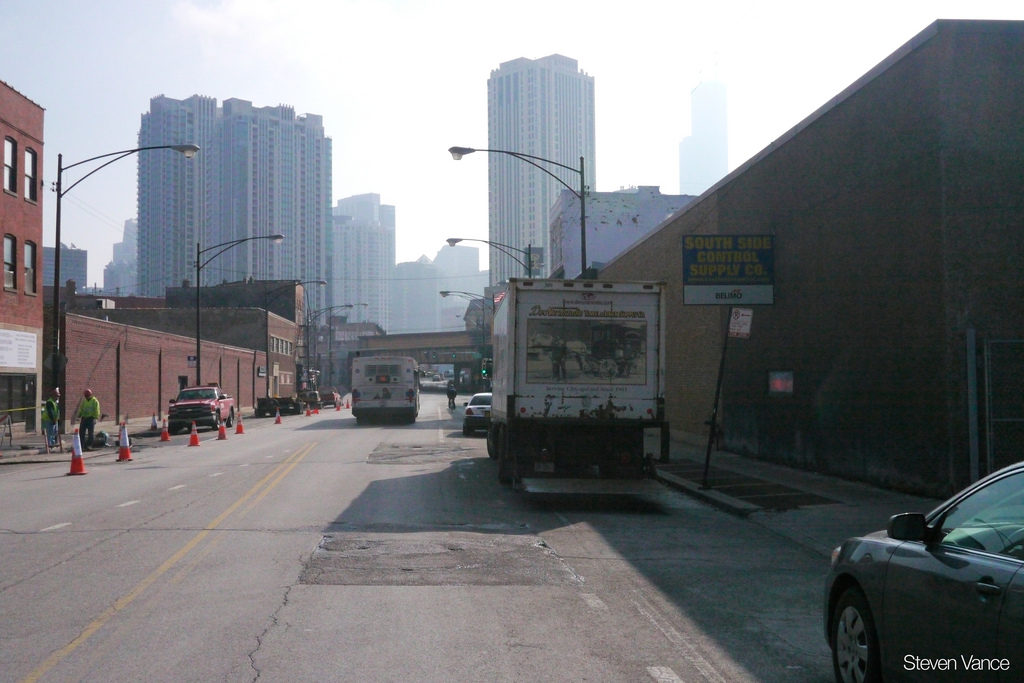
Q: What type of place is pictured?
A: It is a street.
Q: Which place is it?
A: It is a street.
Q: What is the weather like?
A: It is sunny.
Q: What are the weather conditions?
A: It is sunny.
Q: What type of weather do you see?
A: It is sunny.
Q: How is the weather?
A: It is sunny.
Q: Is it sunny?
A: Yes, it is sunny.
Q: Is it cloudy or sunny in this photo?
A: It is sunny.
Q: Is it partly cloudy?
A: No, it is sunny.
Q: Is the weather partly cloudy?
A: No, it is sunny.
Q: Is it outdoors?
A: Yes, it is outdoors.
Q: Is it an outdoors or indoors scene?
A: It is outdoors.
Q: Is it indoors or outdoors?
A: It is outdoors.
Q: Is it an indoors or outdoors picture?
A: It is outdoors.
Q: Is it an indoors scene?
A: No, it is outdoors.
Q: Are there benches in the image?
A: No, there are no benches.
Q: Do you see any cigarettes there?
A: No, there are no cigarettes.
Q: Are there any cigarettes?
A: No, there are no cigarettes.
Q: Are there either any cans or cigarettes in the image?
A: No, there are no cigarettes or cans.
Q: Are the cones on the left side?
A: Yes, the cones are on the left of the image.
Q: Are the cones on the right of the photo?
A: No, the cones are on the left of the image.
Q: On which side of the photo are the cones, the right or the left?
A: The cones are on the left of the image.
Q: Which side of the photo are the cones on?
A: The cones are on the left of the image.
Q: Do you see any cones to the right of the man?
A: Yes, there are cones to the right of the man.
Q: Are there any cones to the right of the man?
A: Yes, there are cones to the right of the man.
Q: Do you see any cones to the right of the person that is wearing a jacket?
A: Yes, there are cones to the right of the man.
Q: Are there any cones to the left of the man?
A: No, the cones are to the right of the man.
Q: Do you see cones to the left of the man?
A: No, the cones are to the right of the man.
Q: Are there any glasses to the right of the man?
A: No, there are cones to the right of the man.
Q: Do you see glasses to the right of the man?
A: No, there are cones to the right of the man.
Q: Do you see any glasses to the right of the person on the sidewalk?
A: No, there are cones to the right of the man.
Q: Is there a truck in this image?
A: Yes, there is a truck.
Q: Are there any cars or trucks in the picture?
A: Yes, there is a truck.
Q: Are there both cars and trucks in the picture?
A: Yes, there are both a truck and cars.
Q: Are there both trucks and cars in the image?
A: Yes, there are both a truck and cars.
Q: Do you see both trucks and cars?
A: Yes, there are both a truck and cars.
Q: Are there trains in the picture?
A: No, there are no trains.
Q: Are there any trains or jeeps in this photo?
A: No, there are no trains or jeeps.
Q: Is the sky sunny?
A: Yes, the sky is sunny.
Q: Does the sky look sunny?
A: Yes, the sky is sunny.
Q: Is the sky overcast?
A: No, the sky is sunny.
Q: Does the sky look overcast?
A: No, the sky is sunny.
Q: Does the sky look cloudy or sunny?
A: The sky is sunny.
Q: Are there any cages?
A: No, there are no cages.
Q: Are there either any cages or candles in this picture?
A: No, there are no cages or candles.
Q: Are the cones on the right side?
A: No, the cones are on the left of the image.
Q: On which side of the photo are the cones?
A: The cones are on the left of the image.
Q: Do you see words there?
A: Yes, there are words.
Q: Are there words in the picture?
A: Yes, there are words.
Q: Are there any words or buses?
A: Yes, there are words.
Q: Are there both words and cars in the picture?
A: Yes, there are both words and a car.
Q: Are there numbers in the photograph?
A: No, there are no numbers.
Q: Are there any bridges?
A: Yes, there is a bridge.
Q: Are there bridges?
A: Yes, there is a bridge.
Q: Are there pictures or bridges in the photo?
A: Yes, there is a bridge.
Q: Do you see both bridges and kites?
A: No, there is a bridge but no kites.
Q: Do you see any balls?
A: No, there are no balls.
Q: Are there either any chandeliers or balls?
A: No, there are no balls or chandeliers.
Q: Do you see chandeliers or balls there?
A: No, there are no balls or chandeliers.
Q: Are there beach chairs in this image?
A: No, there are no beach chairs.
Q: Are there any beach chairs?
A: No, there are no beach chairs.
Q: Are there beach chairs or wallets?
A: No, there are no beach chairs or wallets.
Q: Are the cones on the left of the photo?
A: Yes, the cones are on the left of the image.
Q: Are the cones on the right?
A: No, the cones are on the left of the image.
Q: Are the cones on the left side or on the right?
A: The cones are on the left of the image.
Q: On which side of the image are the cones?
A: The cones are on the left of the image.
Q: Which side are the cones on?
A: The cones are on the left of the image.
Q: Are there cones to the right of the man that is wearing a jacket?
A: Yes, there are cones to the right of the man.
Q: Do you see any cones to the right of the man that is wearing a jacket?
A: Yes, there are cones to the right of the man.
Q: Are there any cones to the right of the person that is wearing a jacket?
A: Yes, there are cones to the right of the man.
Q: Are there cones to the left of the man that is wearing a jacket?
A: No, the cones are to the right of the man.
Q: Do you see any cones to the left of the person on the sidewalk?
A: No, the cones are to the right of the man.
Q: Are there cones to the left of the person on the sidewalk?
A: No, the cones are to the right of the man.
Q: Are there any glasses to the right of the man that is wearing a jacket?
A: No, there are cones to the right of the man.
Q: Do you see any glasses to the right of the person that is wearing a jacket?
A: No, there are cones to the right of the man.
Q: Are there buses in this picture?
A: Yes, there is a bus.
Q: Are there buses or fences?
A: Yes, there is a bus.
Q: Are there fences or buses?
A: Yes, there is a bus.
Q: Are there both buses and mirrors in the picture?
A: Yes, there are both a bus and a mirror.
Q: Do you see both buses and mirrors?
A: Yes, there are both a bus and a mirror.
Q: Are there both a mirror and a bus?
A: Yes, there are both a bus and a mirror.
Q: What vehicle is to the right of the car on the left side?
A: The vehicle is a bus.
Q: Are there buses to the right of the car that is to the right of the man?
A: Yes, there is a bus to the right of the car.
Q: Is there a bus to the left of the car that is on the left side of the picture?
A: No, the bus is to the right of the car.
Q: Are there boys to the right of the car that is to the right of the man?
A: No, there is a bus to the right of the car.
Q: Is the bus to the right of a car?
A: Yes, the bus is to the right of a car.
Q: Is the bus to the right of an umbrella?
A: No, the bus is to the right of a car.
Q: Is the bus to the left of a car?
A: No, the bus is to the right of a car.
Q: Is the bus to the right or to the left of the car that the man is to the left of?
A: The bus is to the right of the car.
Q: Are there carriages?
A: No, there are no carriages.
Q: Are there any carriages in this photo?
A: No, there are no carriages.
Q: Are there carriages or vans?
A: No, there are no carriages or vans.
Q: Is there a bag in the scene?
A: No, there are no bags.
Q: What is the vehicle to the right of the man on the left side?
A: The vehicle is a car.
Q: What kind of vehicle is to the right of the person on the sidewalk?
A: The vehicle is a car.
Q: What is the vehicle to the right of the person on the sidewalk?
A: The vehicle is a car.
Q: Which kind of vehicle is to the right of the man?
A: The vehicle is a car.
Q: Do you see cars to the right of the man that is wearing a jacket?
A: Yes, there is a car to the right of the man.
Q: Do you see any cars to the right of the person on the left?
A: Yes, there is a car to the right of the man.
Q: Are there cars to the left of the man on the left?
A: No, the car is to the right of the man.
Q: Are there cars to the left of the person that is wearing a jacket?
A: No, the car is to the right of the man.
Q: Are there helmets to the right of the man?
A: No, there is a car to the right of the man.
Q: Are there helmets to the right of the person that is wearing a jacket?
A: No, there is a car to the right of the man.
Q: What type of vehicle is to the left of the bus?
A: The vehicle is a car.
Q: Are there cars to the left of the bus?
A: Yes, there is a car to the left of the bus.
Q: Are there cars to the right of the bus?
A: No, the car is to the left of the bus.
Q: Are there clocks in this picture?
A: No, there are no clocks.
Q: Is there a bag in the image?
A: No, there are no bags.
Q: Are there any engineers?
A: No, there are no engineers.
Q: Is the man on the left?
A: Yes, the man is on the left of the image.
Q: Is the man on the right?
A: No, the man is on the left of the image.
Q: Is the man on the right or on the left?
A: The man is on the left of the image.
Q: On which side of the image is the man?
A: The man is on the left of the image.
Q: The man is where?
A: The man is on the sidewalk.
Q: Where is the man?
A: The man is on the sidewalk.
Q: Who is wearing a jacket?
A: The man is wearing a jacket.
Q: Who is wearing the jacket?
A: The man is wearing a jacket.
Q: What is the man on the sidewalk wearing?
A: The man is wearing a jacket.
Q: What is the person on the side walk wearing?
A: The man is wearing a jacket.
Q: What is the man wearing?
A: The man is wearing a jacket.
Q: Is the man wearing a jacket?
A: Yes, the man is wearing a jacket.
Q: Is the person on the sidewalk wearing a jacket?
A: Yes, the man is wearing a jacket.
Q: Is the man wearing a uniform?
A: No, the man is wearing a jacket.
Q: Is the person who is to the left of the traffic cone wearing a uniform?
A: No, the man is wearing a jacket.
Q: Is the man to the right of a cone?
A: No, the man is to the left of a cone.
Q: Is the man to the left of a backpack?
A: No, the man is to the left of a cone.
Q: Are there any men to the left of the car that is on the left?
A: Yes, there is a man to the left of the car.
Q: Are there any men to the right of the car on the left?
A: No, the man is to the left of the car.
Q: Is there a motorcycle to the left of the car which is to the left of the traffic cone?
A: No, there is a man to the left of the car.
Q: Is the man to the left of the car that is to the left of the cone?
A: Yes, the man is to the left of the car.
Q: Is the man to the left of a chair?
A: No, the man is to the left of the car.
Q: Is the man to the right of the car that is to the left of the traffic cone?
A: No, the man is to the left of the car.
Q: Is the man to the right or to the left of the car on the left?
A: The man is to the left of the car.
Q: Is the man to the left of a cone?
A: Yes, the man is to the left of a cone.